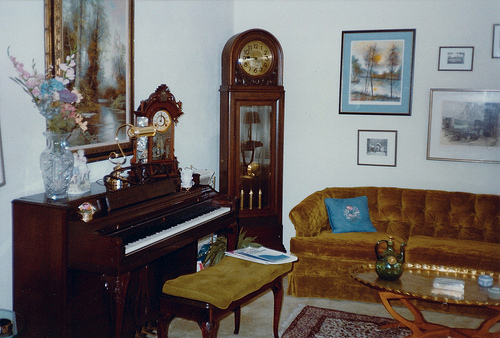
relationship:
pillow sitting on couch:
[323, 197, 378, 234] [288, 180, 498, 301]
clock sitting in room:
[238, 40, 272, 80] [2, 0, 491, 337]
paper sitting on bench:
[223, 243, 298, 264] [160, 242, 297, 337]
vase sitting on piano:
[39, 130, 75, 198] [9, 178, 237, 338]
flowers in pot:
[6, 40, 90, 203] [39, 128, 76, 200]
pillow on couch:
[323, 197, 378, 234] [287, 165, 496, 313]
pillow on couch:
[323, 197, 378, 234] [283, 176, 493, 316]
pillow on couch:
[310, 189, 411, 243] [283, 176, 493, 316]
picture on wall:
[340, 26, 413, 110] [233, 0, 498, 269]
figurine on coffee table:
[374, 234, 406, 279] [350, 260, 498, 336]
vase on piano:
[39, 130, 75, 198] [9, 178, 237, 338]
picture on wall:
[357, 129, 397, 164] [306, 118, 333, 179]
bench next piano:
[167, 202, 303, 337] [9, 178, 237, 338]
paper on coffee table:
[433, 271, 469, 295] [350, 260, 498, 336]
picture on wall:
[426, 85, 498, 167] [233, 5, 496, 196]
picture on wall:
[437, 44, 476, 73] [233, 5, 496, 196]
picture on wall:
[340, 26, 413, 121] [233, 5, 496, 196]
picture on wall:
[357, 129, 397, 164] [233, 5, 496, 196]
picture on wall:
[40, 4, 143, 162] [0, 2, 232, 179]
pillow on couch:
[323, 197, 378, 234] [284, 180, 499, 288]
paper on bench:
[223, 233, 302, 271] [160, 242, 297, 337]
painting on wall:
[336, 23, 421, 125] [297, 28, 344, 170]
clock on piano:
[135, 84, 185, 179] [9, 178, 237, 338]